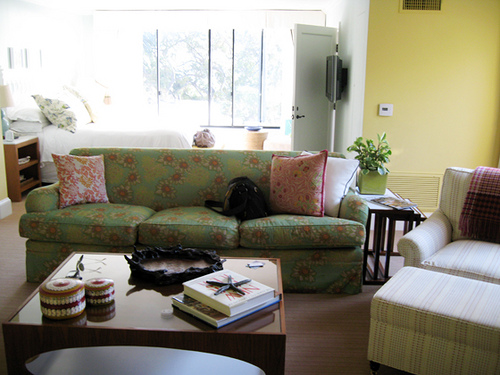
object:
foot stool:
[366, 361, 382, 375]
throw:
[455, 167, 498, 241]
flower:
[287, 262, 323, 283]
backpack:
[204, 174, 268, 221]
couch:
[18, 145, 369, 295]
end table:
[344, 191, 427, 285]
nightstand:
[8, 127, 48, 203]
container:
[85, 278, 114, 309]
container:
[35, 276, 85, 317]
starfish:
[204, 272, 250, 303]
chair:
[395, 164, 500, 284]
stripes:
[395, 273, 498, 314]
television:
[326, 53, 348, 106]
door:
[289, 23, 334, 155]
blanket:
[458, 164, 499, 242]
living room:
[0, 0, 499, 374]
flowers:
[125, 171, 140, 187]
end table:
[4, 136, 42, 202]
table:
[1, 135, 43, 203]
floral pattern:
[152, 151, 181, 166]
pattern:
[123, 212, 141, 230]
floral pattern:
[26, 216, 60, 221]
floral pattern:
[109, 207, 131, 218]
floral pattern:
[199, 186, 224, 202]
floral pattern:
[158, 182, 172, 193]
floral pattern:
[315, 224, 345, 245]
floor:
[307, 306, 336, 368]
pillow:
[50, 153, 107, 208]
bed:
[0, 65, 226, 185]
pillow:
[27, 84, 97, 134]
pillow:
[265, 149, 329, 218]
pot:
[353, 168, 388, 196]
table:
[354, 185, 428, 286]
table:
[0, 250, 288, 374]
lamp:
[0, 80, 18, 139]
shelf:
[13, 153, 43, 172]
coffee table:
[1, 251, 289, 372]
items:
[36, 273, 121, 321]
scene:
[0, 0, 499, 375]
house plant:
[345, 132, 392, 176]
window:
[0, 5, 328, 131]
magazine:
[363, 195, 418, 212]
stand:
[358, 186, 427, 285]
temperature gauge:
[379, 103, 393, 116]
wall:
[352, 0, 499, 179]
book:
[170, 269, 282, 328]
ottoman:
[369, 267, 499, 375]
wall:
[328, 2, 371, 165]